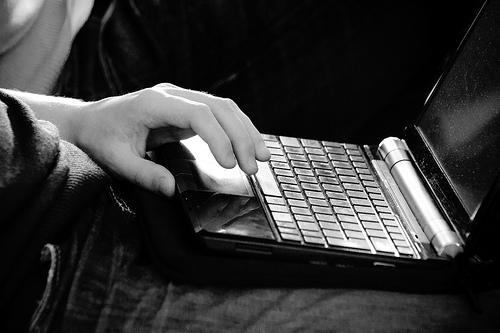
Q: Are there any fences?
A: No, there are no fences.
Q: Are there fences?
A: No, there are no fences.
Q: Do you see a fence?
A: No, there are no fences.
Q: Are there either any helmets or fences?
A: No, there are no fences or helmets.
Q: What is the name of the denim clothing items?
A: The clothing items are pants.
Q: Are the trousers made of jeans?
A: Yes, the trousers are made of jeans.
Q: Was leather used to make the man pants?
A: No, the trousers are made of jeans.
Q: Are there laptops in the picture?
A: Yes, there is a laptop.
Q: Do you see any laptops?
A: Yes, there is a laptop.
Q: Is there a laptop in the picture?
A: Yes, there is a laptop.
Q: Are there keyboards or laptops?
A: Yes, there is a laptop.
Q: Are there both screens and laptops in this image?
A: Yes, there are both a laptop and a screen.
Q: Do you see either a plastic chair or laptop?
A: Yes, there is a plastic laptop.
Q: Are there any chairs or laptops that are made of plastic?
A: Yes, the laptop is made of plastic.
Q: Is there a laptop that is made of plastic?
A: Yes, there is a laptop that is made of plastic.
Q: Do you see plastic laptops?
A: Yes, there is a laptop that is made of plastic.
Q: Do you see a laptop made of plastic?
A: Yes, there is a laptop that is made of plastic.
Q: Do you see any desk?
A: No, there are no desks.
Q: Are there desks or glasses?
A: No, there are no desks or glasses.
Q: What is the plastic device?
A: The device is a laptop.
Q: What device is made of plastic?
A: The device is a laptop.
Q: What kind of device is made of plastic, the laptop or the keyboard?
A: The laptop is made of plastic.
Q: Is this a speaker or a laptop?
A: This is a laptop.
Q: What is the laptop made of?
A: The laptop computer is made of plastic.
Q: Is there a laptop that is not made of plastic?
A: No, there is a laptop but it is made of plastic.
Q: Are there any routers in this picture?
A: No, there are no routers.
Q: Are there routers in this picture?
A: No, there are no routers.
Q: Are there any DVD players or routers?
A: No, there are no routers or DVD players.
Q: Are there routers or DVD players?
A: No, there are no routers or DVD players.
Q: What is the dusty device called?
A: The device is a screen.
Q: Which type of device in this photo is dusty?
A: The device is a screen.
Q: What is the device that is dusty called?
A: The device is a screen.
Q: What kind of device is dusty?
A: The device is a screen.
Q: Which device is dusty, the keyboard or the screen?
A: The screen is dusty.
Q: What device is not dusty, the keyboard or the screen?
A: The keyboard is not dusty.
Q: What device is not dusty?
A: The device is a keyboard.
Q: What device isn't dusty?
A: The device is a keyboard.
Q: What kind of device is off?
A: The device is a screen.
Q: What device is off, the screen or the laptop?
A: The screen is off.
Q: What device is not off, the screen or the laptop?
A: The laptop is not off.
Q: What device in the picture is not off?
A: The device is a laptop.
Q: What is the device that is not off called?
A: The device is a laptop.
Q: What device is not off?
A: The device is a laptop.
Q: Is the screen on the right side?
A: Yes, the screen is on the right of the image.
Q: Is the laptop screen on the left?
A: No, the screen is on the right of the image.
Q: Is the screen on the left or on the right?
A: The screen is on the right of the image.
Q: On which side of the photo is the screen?
A: The screen is on the right of the image.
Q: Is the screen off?
A: Yes, the screen is off.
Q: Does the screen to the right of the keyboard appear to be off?
A: Yes, the screen is off.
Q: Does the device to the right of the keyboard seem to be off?
A: Yes, the screen is off.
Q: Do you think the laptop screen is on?
A: No, the screen is off.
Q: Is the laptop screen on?
A: No, the screen is off.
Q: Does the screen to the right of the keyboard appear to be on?
A: No, the screen is off.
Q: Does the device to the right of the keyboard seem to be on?
A: No, the screen is off.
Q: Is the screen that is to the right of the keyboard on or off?
A: The screen is off.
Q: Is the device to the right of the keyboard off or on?
A: The screen is off.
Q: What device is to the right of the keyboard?
A: The device is a screen.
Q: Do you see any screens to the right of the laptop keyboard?
A: Yes, there is a screen to the right of the keyboard.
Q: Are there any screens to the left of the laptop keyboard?
A: No, the screen is to the right of the keyboard.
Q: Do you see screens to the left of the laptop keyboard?
A: No, the screen is to the right of the keyboard.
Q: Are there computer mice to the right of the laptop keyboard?
A: No, there is a screen to the right of the keyboard.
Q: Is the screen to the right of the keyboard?
A: Yes, the screen is to the right of the keyboard.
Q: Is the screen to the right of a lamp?
A: No, the screen is to the right of the keyboard.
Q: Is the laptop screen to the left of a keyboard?
A: No, the screen is to the right of a keyboard.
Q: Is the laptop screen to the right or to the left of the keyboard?
A: The screen is to the right of the keyboard.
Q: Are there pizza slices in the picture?
A: No, there are no pizza slices.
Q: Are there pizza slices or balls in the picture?
A: No, there are no pizza slices or balls.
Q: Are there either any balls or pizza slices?
A: No, there are no pizza slices or balls.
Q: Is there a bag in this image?
A: Yes, there is a bag.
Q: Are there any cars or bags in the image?
A: Yes, there is a bag.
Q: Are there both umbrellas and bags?
A: No, there is a bag but no umbrellas.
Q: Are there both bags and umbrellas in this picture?
A: No, there is a bag but no umbrellas.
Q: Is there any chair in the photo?
A: No, there are no chairs.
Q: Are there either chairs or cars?
A: No, there are no chairs or cars.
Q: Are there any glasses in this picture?
A: No, there are no glasses.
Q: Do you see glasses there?
A: No, there are no glasses.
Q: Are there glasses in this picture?
A: No, there are no glasses.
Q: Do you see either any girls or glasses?
A: No, there are no glasses or girls.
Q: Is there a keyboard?
A: Yes, there is a keyboard.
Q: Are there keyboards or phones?
A: Yes, there is a keyboard.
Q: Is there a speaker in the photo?
A: No, there are no speakers.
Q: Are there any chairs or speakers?
A: No, there are no speakers or chairs.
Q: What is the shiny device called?
A: The device is a keyboard.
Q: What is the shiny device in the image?
A: The device is a keyboard.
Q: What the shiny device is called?
A: The device is a keyboard.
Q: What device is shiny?
A: The device is a keyboard.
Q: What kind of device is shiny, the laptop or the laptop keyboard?
A: The keyboard is shiny.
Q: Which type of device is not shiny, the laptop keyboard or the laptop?
A: The laptop is not shiny.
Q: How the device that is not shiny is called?
A: The device is a laptop.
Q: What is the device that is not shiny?
A: The device is a laptop.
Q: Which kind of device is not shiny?
A: The device is a laptop.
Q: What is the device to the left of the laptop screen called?
A: The device is a keyboard.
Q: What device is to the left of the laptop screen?
A: The device is a keyboard.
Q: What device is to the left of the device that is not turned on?
A: The device is a keyboard.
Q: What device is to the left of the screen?
A: The device is a keyboard.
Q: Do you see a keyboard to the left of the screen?
A: Yes, there is a keyboard to the left of the screen.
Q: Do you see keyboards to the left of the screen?
A: Yes, there is a keyboard to the left of the screen.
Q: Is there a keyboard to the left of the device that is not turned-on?
A: Yes, there is a keyboard to the left of the screen.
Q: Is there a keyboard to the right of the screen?
A: No, the keyboard is to the left of the screen.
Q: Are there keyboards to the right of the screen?
A: No, the keyboard is to the left of the screen.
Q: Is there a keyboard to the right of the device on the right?
A: No, the keyboard is to the left of the screen.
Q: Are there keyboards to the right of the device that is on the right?
A: No, the keyboard is to the left of the screen.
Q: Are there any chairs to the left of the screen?
A: No, there is a keyboard to the left of the screen.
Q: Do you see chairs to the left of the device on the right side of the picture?
A: No, there is a keyboard to the left of the screen.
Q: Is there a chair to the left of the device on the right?
A: No, there is a keyboard to the left of the screen.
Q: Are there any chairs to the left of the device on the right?
A: No, there is a keyboard to the left of the screen.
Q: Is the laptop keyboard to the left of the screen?
A: Yes, the keyboard is to the left of the screen.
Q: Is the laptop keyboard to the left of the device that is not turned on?
A: Yes, the keyboard is to the left of the screen.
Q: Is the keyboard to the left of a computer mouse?
A: No, the keyboard is to the left of the screen.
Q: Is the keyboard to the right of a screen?
A: No, the keyboard is to the left of a screen.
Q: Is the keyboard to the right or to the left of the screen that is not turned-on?
A: The keyboard is to the left of the screen.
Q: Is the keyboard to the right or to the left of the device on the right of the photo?
A: The keyboard is to the left of the screen.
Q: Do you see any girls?
A: No, there are no girls.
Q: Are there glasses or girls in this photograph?
A: No, there are no girls or glasses.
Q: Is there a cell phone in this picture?
A: No, there are no cell phones.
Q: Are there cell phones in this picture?
A: No, there are no cell phones.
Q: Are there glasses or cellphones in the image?
A: No, there are no cellphones or glasses.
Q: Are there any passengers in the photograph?
A: No, there are no passengers.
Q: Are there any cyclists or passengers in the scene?
A: No, there are no passengers or cyclists.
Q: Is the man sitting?
A: Yes, the man is sitting.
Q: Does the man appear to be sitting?
A: Yes, the man is sitting.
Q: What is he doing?
A: The man is sitting.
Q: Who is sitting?
A: The man is sitting.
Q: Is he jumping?
A: No, the man is sitting.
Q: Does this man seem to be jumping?
A: No, the man is sitting.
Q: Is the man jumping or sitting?
A: The man is sitting.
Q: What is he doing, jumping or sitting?
A: The man is sitting.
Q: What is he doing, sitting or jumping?
A: The man is sitting.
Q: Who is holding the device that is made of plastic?
A: The man is holding the laptop.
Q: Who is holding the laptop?
A: The man is holding the laptop.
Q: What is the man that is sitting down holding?
A: The man is holding the laptop computer.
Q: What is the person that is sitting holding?
A: The man is holding the laptop computer.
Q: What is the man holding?
A: The man is holding the laptop computer.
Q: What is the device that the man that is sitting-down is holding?
A: The device is a laptop.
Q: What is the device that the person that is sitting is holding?
A: The device is a laptop.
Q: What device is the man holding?
A: The man is holding the laptop.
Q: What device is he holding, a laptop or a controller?
A: The man is holding a laptop.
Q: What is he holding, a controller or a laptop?
A: The man is holding a laptop.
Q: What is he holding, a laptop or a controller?
A: The man is holding a laptop.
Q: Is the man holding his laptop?
A: Yes, the man is holding the laptop.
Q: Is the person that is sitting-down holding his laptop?
A: Yes, the man is holding the laptop.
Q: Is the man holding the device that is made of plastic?
A: Yes, the man is holding the laptop.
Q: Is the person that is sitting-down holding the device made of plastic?
A: Yes, the man is holding the laptop.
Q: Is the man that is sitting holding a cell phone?
A: No, the man is holding the laptop.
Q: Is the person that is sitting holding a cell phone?
A: No, the man is holding the laptop.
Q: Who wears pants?
A: The man wears pants.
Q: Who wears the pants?
A: The man wears pants.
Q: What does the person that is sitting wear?
A: The man wears trousers.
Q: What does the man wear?
A: The man wears trousers.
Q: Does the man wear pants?
A: Yes, the man wears pants.